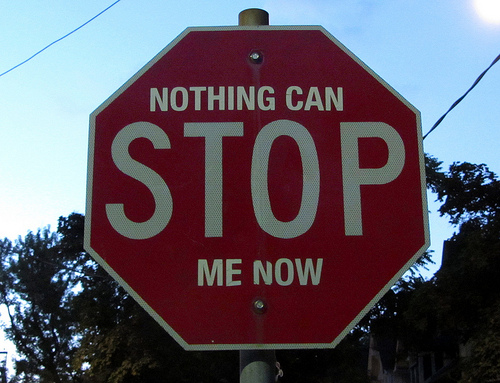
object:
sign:
[84, 22, 430, 353]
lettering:
[105, 86, 405, 287]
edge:
[189, 25, 322, 33]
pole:
[238, 8, 278, 382]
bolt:
[249, 50, 263, 64]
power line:
[0, 1, 125, 76]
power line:
[422, 52, 498, 141]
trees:
[0, 210, 128, 383]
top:
[238, 7, 270, 26]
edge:
[317, 23, 423, 111]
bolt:
[252, 299, 268, 314]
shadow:
[237, 351, 284, 371]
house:
[363, 238, 500, 382]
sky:
[1, 2, 498, 383]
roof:
[370, 315, 464, 350]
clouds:
[0, 179, 81, 238]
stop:
[105, 120, 406, 241]